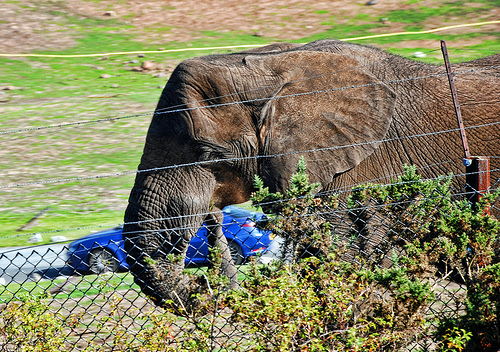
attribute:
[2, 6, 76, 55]
patch — brown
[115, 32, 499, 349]
elephant — old, brown, big, wrinkled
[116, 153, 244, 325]
wrinkled trunk — wide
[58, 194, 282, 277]
car — blue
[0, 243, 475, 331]
road — light grey, paved, grey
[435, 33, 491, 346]
pole — red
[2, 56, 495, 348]
fence — barbed wire, wire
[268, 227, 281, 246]
plate — yellow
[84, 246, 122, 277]
tire — black, silver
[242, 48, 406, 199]
left ear — flat